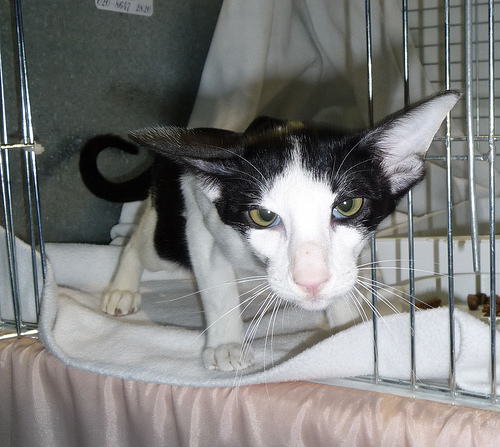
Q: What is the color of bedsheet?
A: Cream.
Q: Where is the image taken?
A: Near to the cat hut.